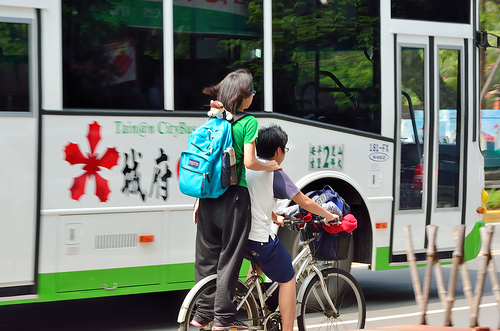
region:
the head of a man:
[254, 118, 293, 163]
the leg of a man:
[255, 234, 302, 329]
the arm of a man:
[274, 165, 328, 222]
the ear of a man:
[274, 143, 284, 156]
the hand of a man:
[323, 206, 342, 226]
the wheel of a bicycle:
[296, 263, 376, 329]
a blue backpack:
[175, 109, 241, 198]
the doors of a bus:
[388, 20, 470, 266]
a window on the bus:
[267, 1, 386, 138]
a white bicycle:
[168, 197, 366, 329]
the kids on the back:
[181, 67, 339, 329]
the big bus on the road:
[0, 2, 491, 291]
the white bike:
[187, 215, 363, 329]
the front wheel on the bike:
[300, 267, 365, 327]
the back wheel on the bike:
[176, 277, 248, 327]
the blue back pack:
[178, 117, 233, 198]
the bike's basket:
[303, 217, 351, 259]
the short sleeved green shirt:
[211, 110, 258, 185]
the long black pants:
[190, 181, 250, 318]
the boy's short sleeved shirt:
[246, 157, 298, 244]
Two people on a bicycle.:
[146, 47, 382, 328]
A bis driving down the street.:
[5, 2, 471, 319]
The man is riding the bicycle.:
[220, 105, 338, 327]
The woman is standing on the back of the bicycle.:
[180, 60, 266, 327]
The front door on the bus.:
[391, 25, 471, 255]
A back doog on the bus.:
[0, 5, 61, 301]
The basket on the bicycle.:
[293, 185, 363, 266]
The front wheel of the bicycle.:
[291, 262, 374, 328]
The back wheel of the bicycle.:
[170, 263, 266, 328]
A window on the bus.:
[56, 0, 174, 115]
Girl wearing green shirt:
[236, 126, 253, 135]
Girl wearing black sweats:
[223, 199, 233, 241]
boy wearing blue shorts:
[268, 249, 285, 269]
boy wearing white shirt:
[256, 173, 265, 194]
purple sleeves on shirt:
[278, 177, 289, 189]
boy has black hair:
[267, 130, 277, 142]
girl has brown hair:
[195, 81, 219, 98]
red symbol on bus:
[57, 120, 119, 200]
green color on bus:
[58, 277, 84, 297]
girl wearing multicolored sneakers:
[208, 318, 254, 328]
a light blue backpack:
[167, 97, 232, 197]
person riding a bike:
[251, 134, 321, 252]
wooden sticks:
[401, 233, 498, 300]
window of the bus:
[68, 49, 158, 94]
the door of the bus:
[390, 69, 469, 219]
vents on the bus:
[90, 230, 152, 257]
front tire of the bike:
[308, 272, 358, 328]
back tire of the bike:
[188, 295, 242, 329]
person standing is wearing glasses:
[241, 84, 264, 96]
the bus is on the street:
[369, 275, 412, 307]